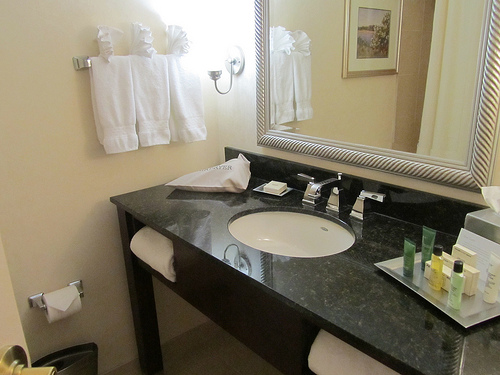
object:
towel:
[165, 52, 212, 145]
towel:
[126, 52, 176, 150]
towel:
[87, 53, 144, 156]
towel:
[162, 23, 194, 61]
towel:
[128, 18, 157, 61]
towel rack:
[71, 52, 97, 71]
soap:
[263, 177, 290, 196]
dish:
[252, 179, 295, 199]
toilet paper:
[40, 283, 84, 325]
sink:
[222, 203, 359, 260]